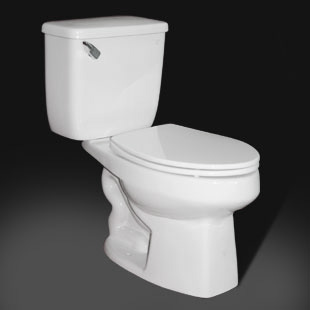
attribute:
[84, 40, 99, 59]
handle — silver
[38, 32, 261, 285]
toilet — gray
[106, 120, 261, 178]
toilet seat — white 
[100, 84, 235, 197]
bowl — white , ceramic 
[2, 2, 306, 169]
black background — black 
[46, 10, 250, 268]
toilet — white 